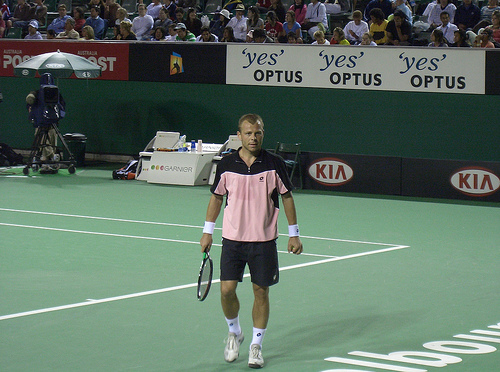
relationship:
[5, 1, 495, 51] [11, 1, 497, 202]
people sitting in stands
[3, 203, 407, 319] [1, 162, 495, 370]
markings on tennis court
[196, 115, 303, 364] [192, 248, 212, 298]
man on tennis racket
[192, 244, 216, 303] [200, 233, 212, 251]
racket in man's hand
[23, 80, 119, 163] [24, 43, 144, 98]
camera with umbrella